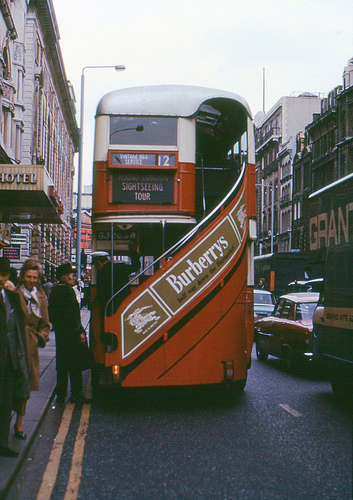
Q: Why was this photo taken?
A: To show the bus.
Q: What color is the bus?
A: Red and silver.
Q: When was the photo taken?
A: During the day.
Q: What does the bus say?
A: Burberrys.